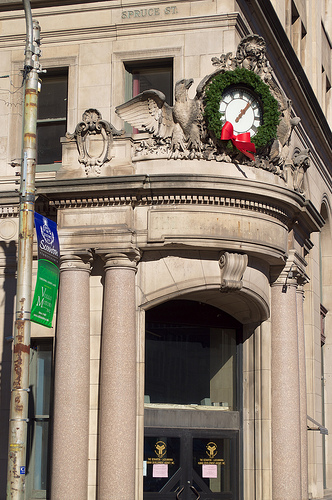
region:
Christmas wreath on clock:
[206, 72, 270, 155]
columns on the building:
[56, 260, 131, 498]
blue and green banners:
[32, 215, 58, 326]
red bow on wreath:
[224, 125, 250, 150]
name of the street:
[119, 7, 189, 18]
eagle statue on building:
[110, 81, 204, 150]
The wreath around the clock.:
[199, 69, 282, 156]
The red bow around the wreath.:
[219, 119, 257, 156]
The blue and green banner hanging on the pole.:
[26, 210, 62, 328]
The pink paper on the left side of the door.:
[150, 464, 168, 478]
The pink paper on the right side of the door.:
[202, 462, 220, 479]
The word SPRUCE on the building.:
[116, 9, 162, 21]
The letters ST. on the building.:
[161, 2, 179, 16]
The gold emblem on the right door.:
[204, 439, 218, 457]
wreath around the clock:
[201, 67, 279, 166]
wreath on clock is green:
[203, 67, 281, 165]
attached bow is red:
[218, 119, 260, 161]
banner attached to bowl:
[24, 211, 60, 339]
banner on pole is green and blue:
[25, 207, 61, 330]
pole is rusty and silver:
[3, 0, 45, 498]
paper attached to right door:
[199, 460, 218, 480]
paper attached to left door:
[151, 460, 169, 482]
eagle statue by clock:
[111, 67, 229, 164]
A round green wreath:
[197, 63, 283, 163]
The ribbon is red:
[212, 117, 257, 164]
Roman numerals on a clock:
[211, 79, 262, 139]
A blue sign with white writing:
[27, 204, 64, 261]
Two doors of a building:
[132, 421, 246, 493]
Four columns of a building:
[42, 240, 314, 494]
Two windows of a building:
[33, 51, 178, 164]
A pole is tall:
[4, 0, 43, 498]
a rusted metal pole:
[0, 20, 39, 498]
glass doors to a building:
[145, 421, 250, 498]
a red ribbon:
[217, 121, 261, 159]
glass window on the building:
[33, 68, 68, 162]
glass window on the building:
[129, 64, 171, 105]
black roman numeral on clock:
[237, 88, 244, 99]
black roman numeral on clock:
[249, 99, 257, 106]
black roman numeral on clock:
[250, 104, 258, 112]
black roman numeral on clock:
[250, 123, 259, 133]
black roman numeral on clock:
[219, 109, 226, 117]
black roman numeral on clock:
[220, 98, 229, 106]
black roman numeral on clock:
[226, 88, 235, 101]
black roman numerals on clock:
[218, 89, 262, 136]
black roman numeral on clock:
[221, 118, 228, 123]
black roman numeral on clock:
[245, 95, 254, 103]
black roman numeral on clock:
[228, 92, 235, 98]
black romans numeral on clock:
[218, 88, 260, 137]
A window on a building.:
[133, 278, 262, 417]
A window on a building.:
[123, 52, 172, 125]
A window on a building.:
[26, 60, 89, 120]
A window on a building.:
[21, 120, 66, 164]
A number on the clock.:
[222, 100, 229, 106]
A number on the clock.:
[227, 93, 235, 101]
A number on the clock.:
[237, 90, 241, 100]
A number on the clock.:
[251, 125, 259, 135]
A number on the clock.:
[252, 117, 263, 120]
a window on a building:
[36, 70, 64, 118]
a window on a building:
[143, 432, 176, 493]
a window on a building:
[192, 436, 232, 492]